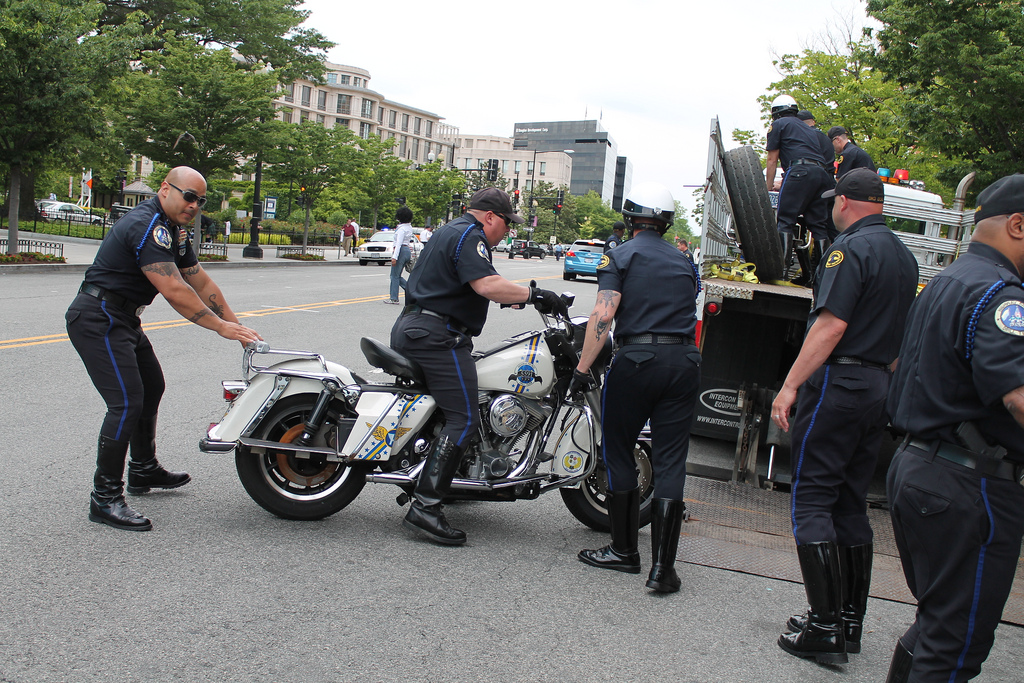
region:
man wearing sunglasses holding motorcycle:
[59, 159, 272, 536]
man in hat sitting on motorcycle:
[382, 183, 576, 553]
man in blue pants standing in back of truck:
[751, 86, 846, 293]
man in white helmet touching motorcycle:
[559, 174, 714, 595]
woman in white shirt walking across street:
[382, 200, 422, 312]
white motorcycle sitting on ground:
[191, 278, 675, 535]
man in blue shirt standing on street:
[877, 162, 1021, 679]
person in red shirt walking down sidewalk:
[335, 211, 362, 265]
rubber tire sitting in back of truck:
[714, 139, 795, 283]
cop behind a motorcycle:
[53, 154, 262, 543]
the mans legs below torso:
[589, 385, 713, 559]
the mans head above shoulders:
[152, 151, 219, 228]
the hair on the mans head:
[165, 168, 184, 184]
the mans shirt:
[92, 205, 198, 310]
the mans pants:
[68, 309, 177, 484]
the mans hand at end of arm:
[232, 320, 262, 363]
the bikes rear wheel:
[238, 383, 365, 517]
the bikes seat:
[343, 314, 426, 382]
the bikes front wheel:
[560, 412, 688, 545]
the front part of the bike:
[523, 301, 670, 564]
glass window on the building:
[275, 81, 291, 95]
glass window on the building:
[295, 77, 315, 104]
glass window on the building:
[311, 106, 322, 123]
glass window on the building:
[327, 90, 351, 114]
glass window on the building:
[356, 93, 376, 122]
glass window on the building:
[318, 68, 338, 84]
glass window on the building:
[371, 125, 390, 148]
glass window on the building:
[386, 107, 400, 133]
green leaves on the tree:
[905, 77, 959, 161]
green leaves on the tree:
[891, 81, 956, 157]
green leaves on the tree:
[354, 135, 390, 161]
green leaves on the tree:
[276, 139, 331, 196]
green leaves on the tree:
[171, 77, 203, 101]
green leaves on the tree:
[159, 55, 242, 117]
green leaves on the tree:
[398, 189, 434, 212]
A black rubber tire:
[230, 388, 384, 538]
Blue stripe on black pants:
[384, 332, 495, 460]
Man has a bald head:
[142, 158, 221, 236]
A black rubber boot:
[384, 435, 487, 557]